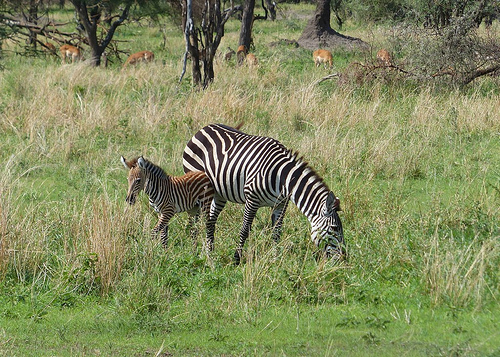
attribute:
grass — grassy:
[2, 6, 498, 349]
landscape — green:
[8, 19, 495, 355]